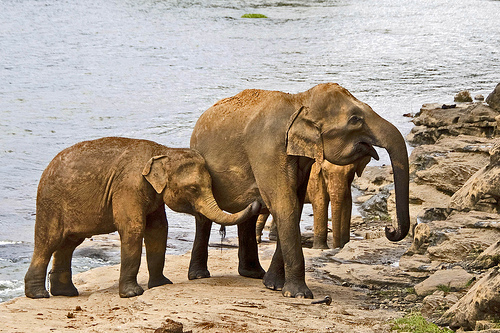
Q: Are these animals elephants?
A: Yes, all the animals are elephants.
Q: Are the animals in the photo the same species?
A: Yes, all the animals are elephants.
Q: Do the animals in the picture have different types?
A: No, all the animals are elephants.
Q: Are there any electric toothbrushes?
A: No, there are no electric toothbrushes.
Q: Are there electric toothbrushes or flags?
A: No, there are no electric toothbrushes or flags.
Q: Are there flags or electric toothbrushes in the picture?
A: No, there are no electric toothbrushes or flags.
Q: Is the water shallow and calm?
A: Yes, the water is shallow and calm.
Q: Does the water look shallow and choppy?
A: No, the water is shallow but calm.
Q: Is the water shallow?
A: Yes, the water is shallow.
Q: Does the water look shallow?
A: Yes, the water is shallow.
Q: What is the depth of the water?
A: The water is shallow.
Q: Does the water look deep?
A: No, the water is shallow.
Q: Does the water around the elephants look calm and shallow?
A: Yes, the water is calm and shallow.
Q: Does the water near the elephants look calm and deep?
A: No, the water is calm but shallow.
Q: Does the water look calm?
A: Yes, the water is calm.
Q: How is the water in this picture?
A: The water is calm.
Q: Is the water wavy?
A: No, the water is calm.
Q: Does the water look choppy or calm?
A: The water is calm.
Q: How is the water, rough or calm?
A: The water is calm.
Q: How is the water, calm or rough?
A: The water is calm.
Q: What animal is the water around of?
A: The water is around the elephants.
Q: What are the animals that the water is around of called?
A: The animals are elephants.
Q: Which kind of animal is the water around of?
A: The water is around the elephants.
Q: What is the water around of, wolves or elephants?
A: The water is around elephants.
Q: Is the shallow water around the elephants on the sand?
A: Yes, the water is around the elephants.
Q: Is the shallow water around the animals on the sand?
A: Yes, the water is around the elephants.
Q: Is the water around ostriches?
A: No, the water is around the elephants.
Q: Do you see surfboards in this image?
A: No, there are no surfboards.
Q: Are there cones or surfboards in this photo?
A: No, there are no surfboards or cones.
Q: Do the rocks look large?
A: Yes, the rocks are large.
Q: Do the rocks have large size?
A: Yes, the rocks are large.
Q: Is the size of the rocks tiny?
A: No, the rocks are large.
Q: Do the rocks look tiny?
A: No, the rocks are large.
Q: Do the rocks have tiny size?
A: No, the rocks are large.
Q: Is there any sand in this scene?
A: Yes, there is sand.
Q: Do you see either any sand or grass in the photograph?
A: Yes, there is sand.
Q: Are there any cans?
A: No, there are no cans.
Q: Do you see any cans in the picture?
A: No, there are no cans.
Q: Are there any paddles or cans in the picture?
A: No, there are no cans or paddles.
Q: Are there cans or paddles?
A: No, there are no cans or paddles.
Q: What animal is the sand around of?
A: The sand is around the elephants.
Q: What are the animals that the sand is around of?
A: The animals are elephants.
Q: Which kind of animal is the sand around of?
A: The sand is around the elephants.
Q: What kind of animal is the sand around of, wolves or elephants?
A: The sand is around elephants.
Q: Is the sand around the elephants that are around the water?
A: Yes, the sand is around the elephants.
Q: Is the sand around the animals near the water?
A: Yes, the sand is around the elephants.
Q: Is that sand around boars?
A: No, the sand is around the elephants.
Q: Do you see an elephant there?
A: Yes, there are elephants.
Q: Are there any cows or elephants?
A: Yes, there are elephants.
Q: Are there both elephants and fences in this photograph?
A: No, there are elephants but no fences.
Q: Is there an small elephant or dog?
A: Yes, there are small elephants.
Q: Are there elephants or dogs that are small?
A: Yes, the elephants are small.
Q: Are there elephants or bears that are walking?
A: Yes, the elephants are walking.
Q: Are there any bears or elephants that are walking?
A: Yes, the elephants are walking.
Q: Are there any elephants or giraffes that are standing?
A: Yes, the elephants are standing.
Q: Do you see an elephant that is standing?
A: Yes, there are elephants that are standing.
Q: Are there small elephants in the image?
A: Yes, there are small elephants.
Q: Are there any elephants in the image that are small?
A: Yes, there are elephants that are small.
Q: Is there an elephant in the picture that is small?
A: Yes, there are elephants that are small.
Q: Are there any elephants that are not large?
A: Yes, there are small elephants.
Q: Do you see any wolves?
A: No, there are no wolves.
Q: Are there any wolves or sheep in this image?
A: No, there are no wolves or sheep.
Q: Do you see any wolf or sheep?
A: No, there are no wolves or sheep.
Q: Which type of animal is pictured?
A: The animal is elephants.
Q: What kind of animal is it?
A: The animals are elephants.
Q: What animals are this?
A: These are elephants.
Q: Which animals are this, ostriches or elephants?
A: These are elephants.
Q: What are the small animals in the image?
A: The animals are elephants.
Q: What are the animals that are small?
A: The animals are elephants.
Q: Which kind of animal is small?
A: The animal is elephants.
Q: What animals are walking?
A: The animals are elephants.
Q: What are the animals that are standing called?
A: The animals are elephants.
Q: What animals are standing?
A: The animals are elephants.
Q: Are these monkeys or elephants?
A: These are elephants.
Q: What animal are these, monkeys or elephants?
A: These are elephants.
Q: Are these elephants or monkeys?
A: These are elephants.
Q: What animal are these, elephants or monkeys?
A: These are elephants.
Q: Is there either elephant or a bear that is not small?
A: No, there are elephants but they are small.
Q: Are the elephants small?
A: Yes, the elephants are small.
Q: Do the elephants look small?
A: Yes, the elephants are small.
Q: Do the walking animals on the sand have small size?
A: Yes, the elephants are small.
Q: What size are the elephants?
A: The elephants are small.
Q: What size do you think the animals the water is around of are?
A: The elephants are small.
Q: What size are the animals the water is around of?
A: The elephants are small.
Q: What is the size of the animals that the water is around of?
A: The elephants are small.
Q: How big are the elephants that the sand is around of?
A: The elephants are small.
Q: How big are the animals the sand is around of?
A: The elephants are small.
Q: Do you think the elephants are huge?
A: No, the elephants are small.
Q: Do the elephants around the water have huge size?
A: No, the elephants are small.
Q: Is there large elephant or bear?
A: No, there are elephants but they are small.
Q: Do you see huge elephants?
A: No, there are elephants but they are small.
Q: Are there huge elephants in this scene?
A: No, there are elephants but they are small.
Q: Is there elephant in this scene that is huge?
A: No, there are elephants but they are small.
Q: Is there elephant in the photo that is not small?
A: No, there are elephants but they are small.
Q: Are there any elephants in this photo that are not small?
A: No, there are elephants but they are small.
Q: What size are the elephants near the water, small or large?
A: The elephants are small.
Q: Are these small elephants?
A: Yes, these are small elephants.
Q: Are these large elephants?
A: No, these are small elephants.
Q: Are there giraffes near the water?
A: No, there are elephants near the water.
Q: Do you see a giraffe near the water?
A: No, there are elephants near the water.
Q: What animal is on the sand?
A: The elephants are on the sand.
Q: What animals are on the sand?
A: The animals are elephants.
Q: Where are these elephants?
A: The elephants are on the sand.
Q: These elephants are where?
A: The elephants are on the sand.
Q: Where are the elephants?
A: The elephants are on the sand.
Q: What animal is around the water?
A: The elephants are around the water.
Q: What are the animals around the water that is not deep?
A: The animals are elephants.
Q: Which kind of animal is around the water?
A: The animals are elephants.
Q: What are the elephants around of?
A: The elephants are around the water.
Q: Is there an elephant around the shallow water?
A: Yes, there are elephants around the water.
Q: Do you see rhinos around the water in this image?
A: No, there are elephants around the water.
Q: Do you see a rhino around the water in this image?
A: No, there are elephants around the water.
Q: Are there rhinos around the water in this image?
A: No, there are elephants around the water.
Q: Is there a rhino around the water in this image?
A: No, there are elephants around the water.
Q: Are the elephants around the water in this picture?
A: Yes, the elephants are around the water.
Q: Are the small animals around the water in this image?
A: Yes, the elephants are around the water.